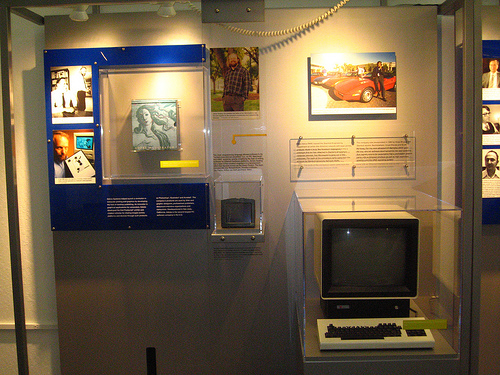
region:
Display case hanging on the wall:
[36, 33, 217, 245]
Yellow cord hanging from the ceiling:
[226, 20, 305, 38]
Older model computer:
[305, 203, 447, 351]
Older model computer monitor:
[312, 201, 424, 310]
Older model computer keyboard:
[308, 304, 434, 355]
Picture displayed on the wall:
[298, 39, 403, 121]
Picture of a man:
[207, 42, 267, 117]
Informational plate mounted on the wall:
[283, 128, 429, 178]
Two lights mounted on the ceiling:
[50, 0, 196, 25]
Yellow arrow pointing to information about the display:
[223, 125, 271, 151]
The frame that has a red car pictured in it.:
[305, 47, 405, 117]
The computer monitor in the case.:
[307, 191, 420, 320]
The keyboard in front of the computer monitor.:
[317, 312, 436, 347]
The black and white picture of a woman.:
[130, 95, 184, 152]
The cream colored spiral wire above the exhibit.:
[161, 4, 369, 49]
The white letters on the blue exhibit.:
[98, 193, 199, 226]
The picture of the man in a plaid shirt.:
[218, 48, 253, 109]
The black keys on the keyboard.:
[322, 318, 402, 343]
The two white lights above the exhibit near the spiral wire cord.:
[70, 10, 182, 28]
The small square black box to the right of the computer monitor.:
[218, 189, 258, 229]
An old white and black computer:
[312, 207, 435, 349]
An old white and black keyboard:
[315, 317, 436, 351]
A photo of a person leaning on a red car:
[310, 51, 399, 117]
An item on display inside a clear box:
[211, 170, 264, 242]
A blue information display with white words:
[43, 45, 210, 228]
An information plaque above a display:
[290, 133, 416, 178]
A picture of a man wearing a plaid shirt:
[211, 45, 261, 112]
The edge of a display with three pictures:
[478, 40, 498, 223]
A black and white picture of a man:
[480, 147, 498, 197]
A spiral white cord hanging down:
[183, 0, 350, 38]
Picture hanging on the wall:
[310, 52, 397, 114]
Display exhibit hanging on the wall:
[42, 46, 211, 231]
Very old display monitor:
[316, 211, 418, 298]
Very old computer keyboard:
[315, 317, 435, 350]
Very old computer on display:
[315, 211, 436, 348]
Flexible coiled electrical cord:
[187, 1, 346, 36]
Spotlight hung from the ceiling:
[67, 4, 88, 21]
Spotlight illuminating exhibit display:
[152, 1, 178, 18]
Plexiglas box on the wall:
[97, 63, 212, 180]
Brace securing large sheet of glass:
[200, 0, 264, 23]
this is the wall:
[56, 257, 191, 325]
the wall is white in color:
[111, 264, 188, 306]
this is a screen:
[305, 210, 429, 283]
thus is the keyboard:
[322, 318, 424, 337]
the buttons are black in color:
[328, 325, 358, 334]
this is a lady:
[136, 104, 171, 140]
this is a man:
[223, 52, 253, 106]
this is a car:
[331, 66, 367, 101]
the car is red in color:
[341, 71, 355, 94]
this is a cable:
[248, 18, 310, 43]